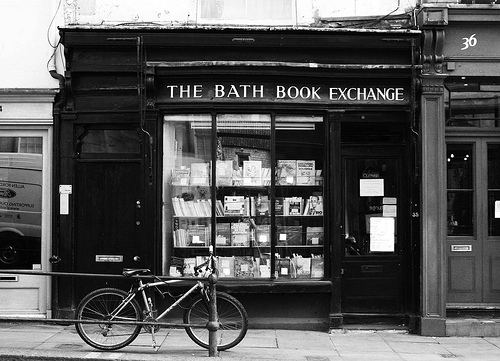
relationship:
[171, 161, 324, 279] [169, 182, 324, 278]
books on shelf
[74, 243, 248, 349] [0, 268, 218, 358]
bike near railing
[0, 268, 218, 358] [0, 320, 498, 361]
railing on sidewalk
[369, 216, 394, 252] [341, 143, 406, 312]
sign on door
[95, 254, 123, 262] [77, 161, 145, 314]
mailbox on door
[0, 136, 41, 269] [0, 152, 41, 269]
window reflects van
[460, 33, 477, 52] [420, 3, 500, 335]
numbers on building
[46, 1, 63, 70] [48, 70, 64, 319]
lines to pipe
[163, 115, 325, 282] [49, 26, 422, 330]
window of store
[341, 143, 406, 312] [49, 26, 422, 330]
door of store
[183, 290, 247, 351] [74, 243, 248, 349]
wheel on bike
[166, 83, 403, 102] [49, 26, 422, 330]
words on store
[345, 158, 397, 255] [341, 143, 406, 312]
windows on door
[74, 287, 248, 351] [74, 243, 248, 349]
wheels of bike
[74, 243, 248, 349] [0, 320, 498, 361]
bike on sidewalk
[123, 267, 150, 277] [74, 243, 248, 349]
seat on bike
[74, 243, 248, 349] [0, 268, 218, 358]
bike on railing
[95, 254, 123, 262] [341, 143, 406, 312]
mailbox on door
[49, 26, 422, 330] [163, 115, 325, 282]
store with window